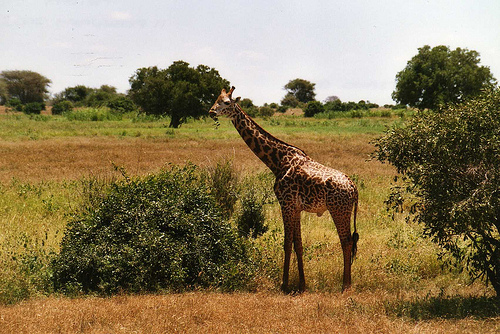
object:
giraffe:
[208, 86, 358, 294]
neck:
[227, 104, 286, 175]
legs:
[277, 194, 300, 292]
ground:
[0, 112, 500, 334]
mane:
[237, 103, 306, 155]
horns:
[221, 86, 228, 94]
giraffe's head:
[208, 86, 243, 119]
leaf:
[149, 82, 154, 85]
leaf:
[184, 94, 189, 99]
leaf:
[183, 79, 186, 83]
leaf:
[151, 106, 157, 110]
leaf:
[179, 64, 184, 68]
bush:
[50, 157, 273, 303]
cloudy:
[0, 0, 500, 104]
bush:
[350, 108, 364, 119]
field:
[0, 107, 495, 334]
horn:
[228, 85, 236, 95]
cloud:
[105, 6, 142, 28]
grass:
[0, 110, 490, 334]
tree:
[126, 59, 231, 131]